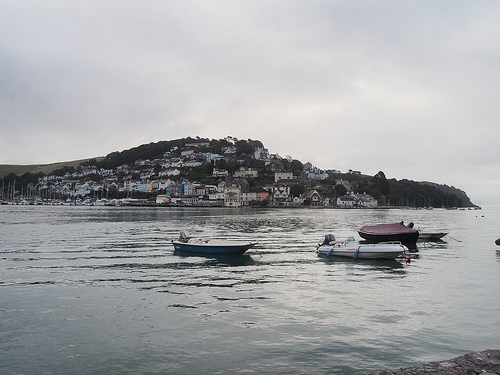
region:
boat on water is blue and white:
[153, 227, 255, 268]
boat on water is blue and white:
[161, 222, 281, 301]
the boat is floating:
[155, 214, 262, 289]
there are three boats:
[153, 174, 439, 292]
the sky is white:
[155, 10, 358, 124]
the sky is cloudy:
[160, 1, 428, 150]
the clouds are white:
[86, 13, 298, 118]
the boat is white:
[314, 222, 419, 283]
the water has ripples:
[67, 223, 134, 292]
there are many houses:
[96, 115, 277, 225]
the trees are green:
[393, 162, 445, 209]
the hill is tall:
[116, 116, 264, 218]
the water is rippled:
[106, 272, 227, 348]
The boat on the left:
[165, 227, 270, 260]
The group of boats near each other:
[167, 211, 497, 276]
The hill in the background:
[0, 132, 485, 214]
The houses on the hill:
[27, 132, 387, 212]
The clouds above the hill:
[0, 2, 495, 204]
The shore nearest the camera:
[305, 346, 498, 374]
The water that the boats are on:
[0, 198, 499, 368]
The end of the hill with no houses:
[374, 164, 479, 210]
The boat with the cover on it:
[355, 215, 419, 246]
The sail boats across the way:
[0, 181, 75, 210]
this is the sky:
[60, 2, 306, 102]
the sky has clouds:
[255, 52, 385, 135]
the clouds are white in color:
[313, 82, 415, 149]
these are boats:
[161, 214, 446, 261]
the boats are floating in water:
[126, 202, 468, 271]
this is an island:
[12, 122, 412, 208]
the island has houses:
[37, 137, 448, 212]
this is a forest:
[382, 172, 452, 206]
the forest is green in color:
[392, 176, 446, 206]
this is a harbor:
[0, 181, 472, 226]